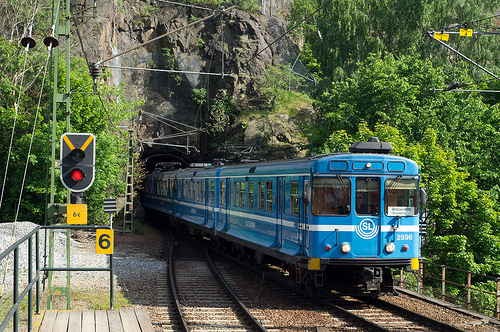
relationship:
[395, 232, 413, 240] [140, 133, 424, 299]
number on train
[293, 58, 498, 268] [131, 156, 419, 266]
trees near train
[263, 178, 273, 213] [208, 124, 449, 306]
window of train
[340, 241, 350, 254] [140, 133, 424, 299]
light in front of train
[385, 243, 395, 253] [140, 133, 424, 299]
light in front of train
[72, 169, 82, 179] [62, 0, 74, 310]
light on post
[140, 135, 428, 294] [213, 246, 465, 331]
train on railroad tracks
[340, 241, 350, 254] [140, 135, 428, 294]
light on train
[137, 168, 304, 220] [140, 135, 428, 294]
windows on train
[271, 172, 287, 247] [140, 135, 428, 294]
door on train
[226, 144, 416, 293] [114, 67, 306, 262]
train in cave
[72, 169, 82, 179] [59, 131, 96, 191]
light on sign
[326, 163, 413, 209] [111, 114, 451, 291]
windshield wipers on train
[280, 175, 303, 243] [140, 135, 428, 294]
door on train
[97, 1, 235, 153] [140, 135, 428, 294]
power lines over train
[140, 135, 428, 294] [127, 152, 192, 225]
train leaves tunnel